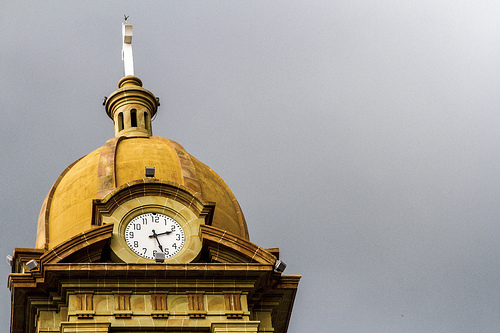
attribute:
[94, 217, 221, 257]
numbers — latin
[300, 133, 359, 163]
sky — blue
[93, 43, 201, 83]
cross — white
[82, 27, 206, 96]
cross — white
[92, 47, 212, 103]
cross — white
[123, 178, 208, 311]
clock — white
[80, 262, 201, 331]
columns — small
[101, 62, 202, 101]
cross — white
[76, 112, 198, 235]
top — domed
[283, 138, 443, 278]
sky — grey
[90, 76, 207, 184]
room — small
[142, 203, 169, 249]
clock — white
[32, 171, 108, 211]
section — yellow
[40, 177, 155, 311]
section — arched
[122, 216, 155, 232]
number — black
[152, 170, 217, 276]
clock — white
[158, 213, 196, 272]
number — black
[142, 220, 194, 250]
number — black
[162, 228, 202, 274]
number — black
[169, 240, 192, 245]
number — black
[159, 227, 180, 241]
number — black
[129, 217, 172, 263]
number — black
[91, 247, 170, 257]
number — black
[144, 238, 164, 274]
number — black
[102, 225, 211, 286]
number — black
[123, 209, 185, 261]
clock — analog, showing 2:27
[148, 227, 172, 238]
hour hand — indicating 2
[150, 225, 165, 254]
minute hand — black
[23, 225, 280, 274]
arch — stone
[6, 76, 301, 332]
roof — yellow, large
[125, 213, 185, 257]
clock — white, black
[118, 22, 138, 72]
cross — large, white, stone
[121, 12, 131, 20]
bird — little, black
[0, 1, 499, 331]
sky — hazy, gray, huuuuge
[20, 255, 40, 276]
light — gray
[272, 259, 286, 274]
light — gray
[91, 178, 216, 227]
arch — stone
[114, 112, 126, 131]
window — small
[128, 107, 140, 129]
window — small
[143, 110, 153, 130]
window — small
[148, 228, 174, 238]
hour hand — black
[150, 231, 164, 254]
minute hand — black